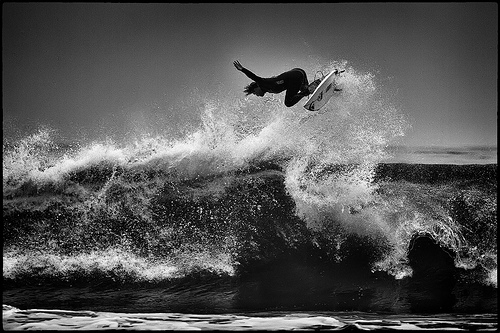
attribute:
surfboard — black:
[299, 61, 347, 113]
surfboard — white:
[304, 69, 345, 111]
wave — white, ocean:
[132, 127, 493, 262]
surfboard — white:
[302, 66, 349, 115]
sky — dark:
[0, 0, 495, 151]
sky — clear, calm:
[15, 7, 491, 190]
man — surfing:
[227, 58, 322, 108]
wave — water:
[7, 137, 493, 308]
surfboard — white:
[302, 69, 357, 115]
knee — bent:
[283, 96, 298, 107]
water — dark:
[267, 227, 359, 300]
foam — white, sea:
[146, 121, 378, 201]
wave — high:
[273, 126, 488, 264]